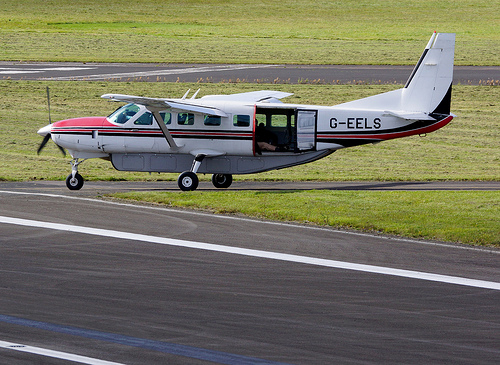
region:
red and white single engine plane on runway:
[29, 22, 463, 196]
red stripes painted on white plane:
[47, 113, 447, 135]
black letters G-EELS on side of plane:
[325, 113, 387, 130]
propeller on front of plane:
[35, 84, 68, 157]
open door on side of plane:
[252, 110, 324, 160]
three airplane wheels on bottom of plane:
[62, 163, 235, 193]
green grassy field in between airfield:
[0, 0, 497, 237]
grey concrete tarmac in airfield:
[4, 175, 499, 360]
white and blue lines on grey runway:
[2, 184, 481, 356]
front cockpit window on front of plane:
[109, 103, 144, 124]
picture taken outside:
[8, 7, 498, 360]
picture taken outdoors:
[23, 23, 485, 360]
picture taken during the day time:
[3, 7, 493, 360]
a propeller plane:
[25, 64, 450, 206]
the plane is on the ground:
[4, 51, 452, 206]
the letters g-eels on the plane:
[319, 103, 386, 133]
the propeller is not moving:
[19, 70, 74, 188]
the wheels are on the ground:
[44, 150, 254, 213]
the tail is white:
[422, 33, 447, 77]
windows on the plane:
[125, 105, 262, 135]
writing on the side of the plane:
[328, 112, 384, 132]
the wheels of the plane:
[62, 169, 236, 192]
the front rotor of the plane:
[34, 87, 68, 158]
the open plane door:
[248, 105, 313, 152]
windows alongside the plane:
[135, 107, 255, 132]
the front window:
[110, 98, 140, 129]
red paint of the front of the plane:
[51, 115, 111, 140]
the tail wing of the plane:
[398, 33, 457, 131]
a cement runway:
[1, 180, 497, 363]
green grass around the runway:
[0, 2, 499, 243]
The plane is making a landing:
[16, 10, 477, 331]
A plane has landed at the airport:
[16, 17, 496, 270]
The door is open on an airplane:
[18, 11, 493, 336]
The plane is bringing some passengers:
[16, 23, 493, 279]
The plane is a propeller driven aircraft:
[10, 10, 486, 280]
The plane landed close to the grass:
[20, 18, 495, 265]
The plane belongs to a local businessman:
[17, 23, 487, 260]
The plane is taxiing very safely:
[25, 21, 491, 282]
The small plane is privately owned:
[15, 16, 485, 251]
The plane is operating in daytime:
[27, 24, 497, 286]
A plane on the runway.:
[33, 49, 478, 186]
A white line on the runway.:
[71, 207, 338, 309]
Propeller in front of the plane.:
[28, 79, 65, 170]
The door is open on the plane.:
[250, 113, 336, 163]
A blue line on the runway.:
[37, 299, 204, 364]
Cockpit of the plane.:
[106, 102, 157, 134]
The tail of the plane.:
[395, 39, 480, 118]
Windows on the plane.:
[156, 110, 268, 142]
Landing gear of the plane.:
[64, 160, 254, 202]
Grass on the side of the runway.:
[348, 198, 473, 249]